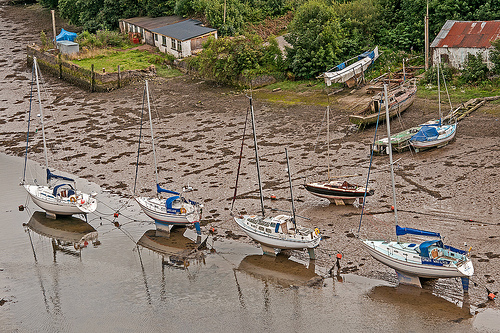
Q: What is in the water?
A: The boats.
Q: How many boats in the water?
A: Four.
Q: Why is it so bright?
A: Sun light.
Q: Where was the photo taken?
A: At a marina.